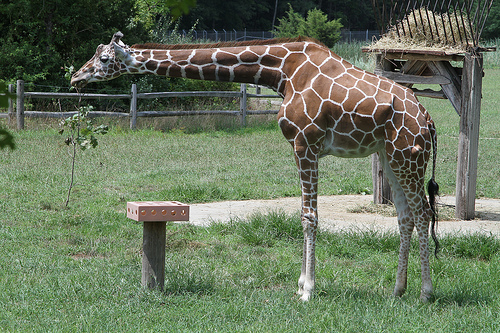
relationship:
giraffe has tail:
[69, 32, 446, 306] [427, 116, 444, 263]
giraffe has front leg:
[69, 32, 446, 306] [294, 127, 322, 307]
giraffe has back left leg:
[69, 32, 446, 306] [392, 146, 438, 308]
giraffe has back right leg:
[69, 32, 446, 306] [380, 151, 415, 300]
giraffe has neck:
[69, 32, 446, 306] [135, 38, 310, 95]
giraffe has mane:
[69, 32, 446, 306] [130, 34, 313, 50]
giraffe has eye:
[69, 32, 446, 306] [98, 54, 112, 66]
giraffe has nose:
[69, 32, 446, 306] [68, 71, 82, 81]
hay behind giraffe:
[366, 6, 475, 70] [69, 32, 446, 306]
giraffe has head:
[69, 32, 446, 306] [67, 30, 139, 88]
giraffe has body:
[69, 32, 446, 306] [277, 52, 434, 158]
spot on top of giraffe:
[311, 71, 337, 103] [69, 32, 446, 306]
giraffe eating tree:
[69, 32, 446, 306] [55, 61, 112, 210]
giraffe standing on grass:
[69, 32, 446, 306] [1, 44, 500, 332]